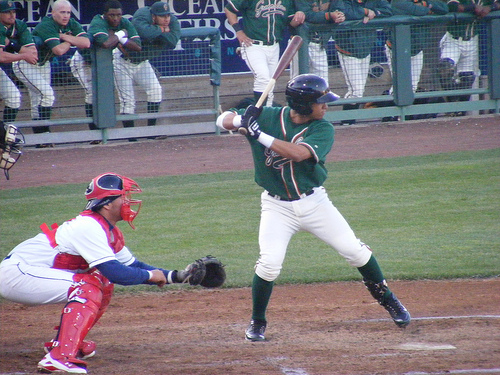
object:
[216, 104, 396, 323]
uniform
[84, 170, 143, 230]
helmet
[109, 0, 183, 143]
players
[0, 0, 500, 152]
dugout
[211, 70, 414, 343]
player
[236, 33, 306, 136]
bat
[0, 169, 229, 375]
catcher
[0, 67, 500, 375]
field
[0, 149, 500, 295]
grass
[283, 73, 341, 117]
helmet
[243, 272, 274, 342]
cleets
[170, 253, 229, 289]
mitt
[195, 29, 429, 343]
baseball.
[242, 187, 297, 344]
legs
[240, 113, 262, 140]
gloves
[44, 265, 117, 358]
shin guards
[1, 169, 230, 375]
player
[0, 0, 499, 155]
fence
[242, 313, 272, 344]
shoes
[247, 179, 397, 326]
pants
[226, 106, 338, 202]
jersey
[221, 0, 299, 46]
jerseys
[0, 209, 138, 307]
white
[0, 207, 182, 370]
outfit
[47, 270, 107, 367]
knee pads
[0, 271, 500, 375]
homeplate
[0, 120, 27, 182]
umpire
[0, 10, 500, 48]
railing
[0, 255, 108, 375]
legs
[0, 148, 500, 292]
patch